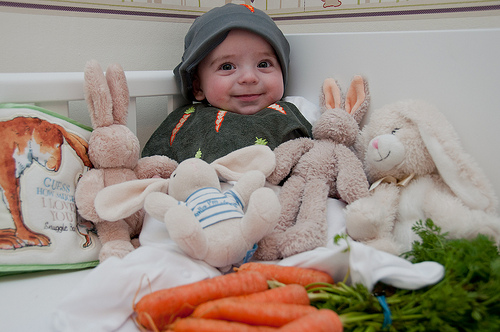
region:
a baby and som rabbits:
[146, 16, 372, 211]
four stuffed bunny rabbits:
[56, 38, 498, 268]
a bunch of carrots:
[113, 246, 495, 328]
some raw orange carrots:
[96, 223, 341, 329]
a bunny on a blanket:
[6, 102, 136, 264]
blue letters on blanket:
[31, 167, 83, 204]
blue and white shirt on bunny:
[166, 166, 277, 251]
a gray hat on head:
[155, 7, 322, 94]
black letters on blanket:
[31, 208, 92, 246]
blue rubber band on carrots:
[363, 285, 415, 329]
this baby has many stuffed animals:
[60, 3, 495, 265]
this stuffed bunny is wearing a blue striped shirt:
[92, 138, 284, 270]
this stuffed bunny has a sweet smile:
[344, 90, 496, 247]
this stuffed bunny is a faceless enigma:
[74, 55, 178, 265]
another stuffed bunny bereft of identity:
[269, 69, 375, 266]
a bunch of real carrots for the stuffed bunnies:
[128, 223, 498, 326]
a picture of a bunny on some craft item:
[1, 91, 109, 278]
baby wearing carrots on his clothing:
[139, 83, 316, 168]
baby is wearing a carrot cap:
[168, 0, 299, 120]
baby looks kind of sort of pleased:
[194, 20, 291, 115]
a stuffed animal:
[298, 90, 353, 239]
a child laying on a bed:
[158, 35, 291, 136]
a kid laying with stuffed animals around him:
[70, 39, 439, 230]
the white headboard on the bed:
[11, 64, 171, 137]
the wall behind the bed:
[8, 19, 167, 67]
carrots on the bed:
[148, 267, 488, 328]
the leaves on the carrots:
[313, 231, 490, 324]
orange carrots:
[153, 268, 323, 325]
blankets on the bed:
[105, 240, 230, 295]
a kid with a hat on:
[171, 17, 293, 143]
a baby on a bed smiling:
[151, 14, 311, 178]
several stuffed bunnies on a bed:
[70, 80, 475, 265]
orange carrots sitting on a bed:
[129, 274, 496, 329]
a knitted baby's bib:
[3, 106, 109, 285]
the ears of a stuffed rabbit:
[311, 74, 378, 121]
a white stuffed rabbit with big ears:
[96, 144, 298, 264]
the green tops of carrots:
[334, 219, 496, 326]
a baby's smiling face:
[171, 0, 299, 116]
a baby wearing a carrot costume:
[145, 0, 325, 160]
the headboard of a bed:
[9, 74, 181, 140]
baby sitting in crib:
[135, 2, 343, 164]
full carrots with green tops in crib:
[120, 215, 499, 330]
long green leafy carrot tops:
[304, 215, 496, 330]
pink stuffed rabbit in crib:
[71, 54, 180, 267]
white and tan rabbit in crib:
[339, 96, 497, 258]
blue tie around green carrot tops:
[367, 290, 397, 330]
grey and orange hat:
[171, 0, 293, 104]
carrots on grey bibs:
[159, 100, 232, 150]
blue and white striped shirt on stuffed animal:
[170, 183, 248, 230]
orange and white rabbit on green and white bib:
[0, 109, 92, 257]